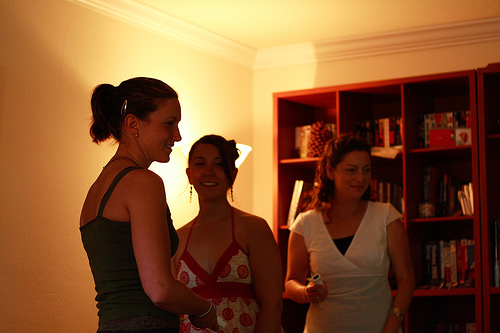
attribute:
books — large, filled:
[280, 89, 481, 155]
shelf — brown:
[262, 69, 484, 316]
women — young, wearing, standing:
[73, 41, 444, 329]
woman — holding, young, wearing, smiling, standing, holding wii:
[260, 111, 389, 325]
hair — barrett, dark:
[211, 120, 238, 161]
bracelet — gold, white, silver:
[383, 293, 410, 321]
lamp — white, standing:
[223, 123, 251, 181]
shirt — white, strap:
[282, 189, 435, 320]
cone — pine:
[301, 96, 337, 166]